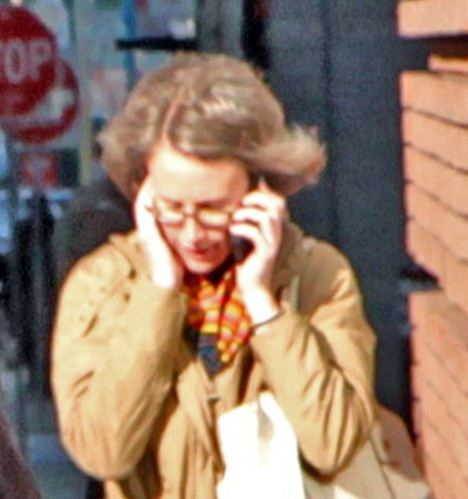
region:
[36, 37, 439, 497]
A woman is talking on the phone.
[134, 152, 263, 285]
The woman is wearing glasses.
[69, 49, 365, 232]
The woman has grayish blond hair.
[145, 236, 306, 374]
The woman is wearing a scarf.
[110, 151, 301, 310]
The woman is holding her hand to her ear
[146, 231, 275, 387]
the scarf is very colorful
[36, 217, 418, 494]
The woman is wearing a jacket.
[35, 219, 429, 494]
The jacket is tan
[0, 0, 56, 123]
A stop sign is in the background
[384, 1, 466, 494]
A brick wall is on the side.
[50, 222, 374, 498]
a light brown coat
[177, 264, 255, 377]
a scarf with orange and pink stripes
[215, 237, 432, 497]
top portion of a large tote bag hung from woman's shoulder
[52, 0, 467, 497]
woman is standing beside a red brick wall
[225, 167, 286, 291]
woman holding a phone to her head with her left hand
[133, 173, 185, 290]
woman's right hand up to her ear to block out sound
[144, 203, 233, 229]
woman's glasses have thick frames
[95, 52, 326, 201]
woman has short, light brown hair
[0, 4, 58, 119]
half of a stop sign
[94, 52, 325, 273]
woman's head is bent slightly downward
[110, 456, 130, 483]
edge of a elbow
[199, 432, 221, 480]
part ogf a coat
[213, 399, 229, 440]
pat of a paper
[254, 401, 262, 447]
part of a shade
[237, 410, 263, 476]
part of a opaper